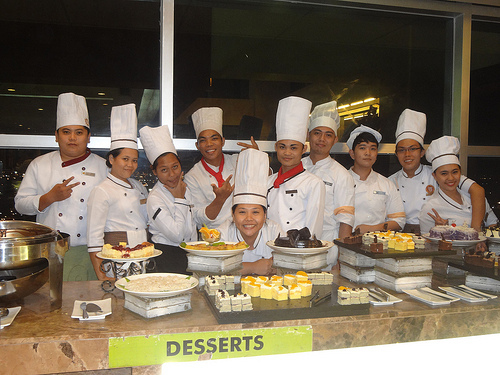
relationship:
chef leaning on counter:
[205, 143, 291, 280] [1, 245, 499, 373]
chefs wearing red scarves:
[183, 102, 235, 237] [194, 157, 232, 185]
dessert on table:
[336, 284, 351, 305] [369, 302, 432, 347]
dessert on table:
[348, 286, 359, 304] [369, 302, 432, 347]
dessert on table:
[358, 284, 370, 304] [369, 302, 432, 347]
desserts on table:
[275, 227, 327, 248] [0, 259, 499, 371]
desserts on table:
[428, 223, 482, 240] [0, 259, 499, 371]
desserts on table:
[359, 232, 429, 251] [0, 259, 499, 371]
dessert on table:
[240, 265, 316, 302] [0, 259, 499, 371]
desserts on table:
[123, 276, 190, 291] [0, 259, 499, 371]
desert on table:
[93, 242, 161, 277] [14, 276, 499, 361]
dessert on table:
[184, 233, 243, 276] [14, 276, 499, 361]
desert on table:
[270, 221, 330, 270] [14, 276, 499, 361]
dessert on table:
[349, 223, 434, 294] [14, 276, 499, 361]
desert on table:
[93, 242, 161, 277] [0, 238, 498, 373]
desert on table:
[113, 270, 198, 317] [0, 238, 498, 373]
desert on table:
[89, 230, 161, 273] [0, 238, 498, 373]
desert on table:
[203, 264, 373, 321] [0, 238, 498, 373]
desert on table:
[270, 221, 330, 270] [0, 238, 498, 373]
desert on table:
[93, 242, 161, 277] [6, 277, 495, 348]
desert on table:
[113, 270, 198, 317] [6, 277, 495, 348]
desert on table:
[203, 264, 373, 321] [6, 277, 495, 348]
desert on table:
[270, 221, 330, 270] [6, 277, 495, 348]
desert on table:
[338, 218, 431, 287] [6, 277, 495, 348]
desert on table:
[333, 218, 458, 291] [0, 238, 498, 373]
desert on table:
[338, 218, 431, 287] [0, 238, 498, 373]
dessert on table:
[330, 279, 373, 305] [0, 238, 498, 373]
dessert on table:
[243, 265, 316, 302] [0, 238, 498, 373]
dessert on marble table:
[270, 285, 290, 300] [311, 300, 498, 350]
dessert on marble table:
[239, 290, 254, 305] [311, 300, 498, 350]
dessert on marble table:
[146, 240, 154, 254] [311, 300, 498, 350]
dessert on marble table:
[370, 242, 382, 253] [311, 300, 498, 350]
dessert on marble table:
[359, 230, 376, 247] [311, 300, 498, 350]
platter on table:
[62, 284, 116, 329] [0, 238, 498, 373]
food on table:
[87, 221, 493, 308] [0, 238, 498, 373]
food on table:
[94, 226, 456, 322] [0, 238, 498, 373]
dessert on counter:
[240, 265, 316, 302] [1, 245, 499, 373]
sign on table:
[110, 320, 325, 374] [0, 238, 498, 373]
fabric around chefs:
[272, 160, 305, 186] [264, 92, 325, 235]